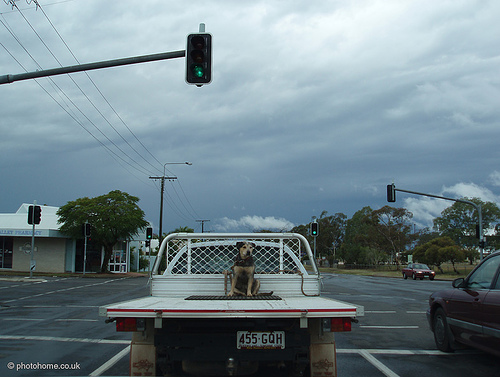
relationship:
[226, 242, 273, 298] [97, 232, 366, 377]
dog on truck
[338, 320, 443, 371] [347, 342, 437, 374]
stripes on road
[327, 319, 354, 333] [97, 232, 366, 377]
tail light on truck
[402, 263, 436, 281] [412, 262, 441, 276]
red car has headlights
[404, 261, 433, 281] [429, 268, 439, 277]
red car has headlight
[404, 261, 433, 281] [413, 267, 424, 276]
red car has headlight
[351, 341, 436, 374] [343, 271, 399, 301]
stripe on road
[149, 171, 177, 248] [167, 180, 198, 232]
telephone pole has wires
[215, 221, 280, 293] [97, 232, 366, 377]
dog on truck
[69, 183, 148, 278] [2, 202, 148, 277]
tree by building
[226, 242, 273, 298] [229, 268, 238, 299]
dog has leg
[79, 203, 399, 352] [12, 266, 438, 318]
truck in intersection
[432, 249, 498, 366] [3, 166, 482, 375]
vehicle going through intersection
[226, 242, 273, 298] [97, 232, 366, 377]
dog on back of truck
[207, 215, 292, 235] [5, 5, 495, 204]
cloud in sky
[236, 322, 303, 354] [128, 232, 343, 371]
license plate on back of truck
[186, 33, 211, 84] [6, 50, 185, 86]
traffic light on pole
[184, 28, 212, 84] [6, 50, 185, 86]
traffic light on pole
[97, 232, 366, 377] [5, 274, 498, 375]
truck on road